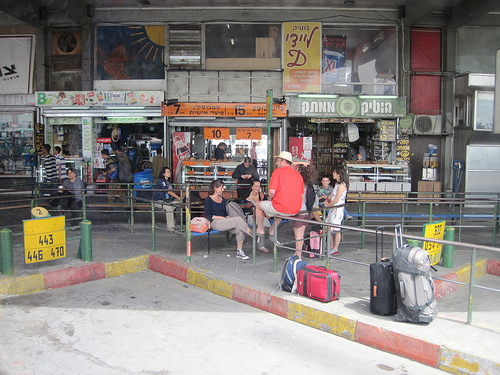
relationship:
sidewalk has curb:
[0, 223, 496, 373] [3, 254, 497, 374]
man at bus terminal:
[250, 146, 306, 240] [4, 7, 498, 371]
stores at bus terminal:
[3, 105, 500, 289] [4, 0, 497, 375]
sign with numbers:
[22, 203, 87, 271] [26, 226, 66, 259]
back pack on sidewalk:
[281, 251, 306, 296] [25, 200, 485, 375]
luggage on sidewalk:
[295, 261, 342, 304] [25, 200, 485, 375]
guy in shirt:
[263, 151, 301, 212] [261, 162, 307, 219]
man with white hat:
[250, 146, 306, 240] [271, 144, 296, 166]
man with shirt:
[246, 133, 317, 291] [226, 143, 313, 243]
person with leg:
[202, 177, 258, 262] [212, 217, 257, 239]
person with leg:
[202, 177, 258, 262] [230, 225, 249, 257]